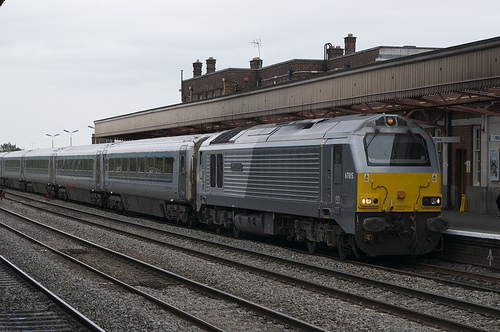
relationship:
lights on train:
[355, 194, 488, 222] [146, 133, 436, 241]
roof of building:
[206, 65, 334, 100] [132, 61, 496, 125]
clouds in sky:
[28, 29, 144, 93] [64, 18, 203, 67]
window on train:
[361, 129, 435, 172] [146, 133, 436, 241]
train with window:
[146, 133, 436, 241] [361, 129, 435, 172]